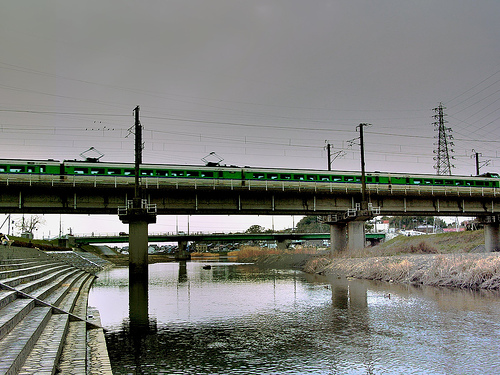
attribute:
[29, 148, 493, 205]
train — green , white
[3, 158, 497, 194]
train — green, long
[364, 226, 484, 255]
grass — some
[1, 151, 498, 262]
bridge — white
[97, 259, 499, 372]
river — calm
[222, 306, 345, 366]
water — green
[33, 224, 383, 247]
bridge — another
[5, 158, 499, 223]
bridge — another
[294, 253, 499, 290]
grass — brown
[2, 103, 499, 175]
wiring — electrical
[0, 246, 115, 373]
steps — stone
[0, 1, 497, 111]
sky — gray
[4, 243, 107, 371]
structure — concrete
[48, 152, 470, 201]
rectangular windows — green, whtie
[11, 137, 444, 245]
bridge — green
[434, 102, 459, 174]
tower — tall, gray, metal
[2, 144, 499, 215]
sky — gray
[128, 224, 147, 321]
column — concrete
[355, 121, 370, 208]
light pole — metal, black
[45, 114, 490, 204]
train — electric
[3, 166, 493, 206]
train — green